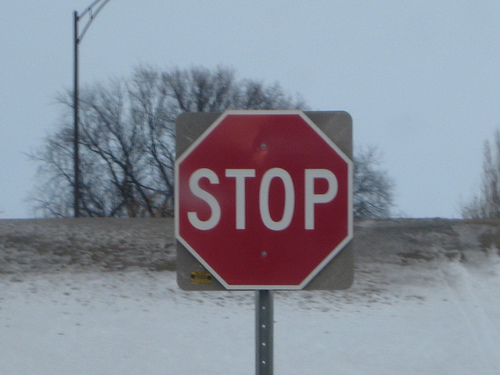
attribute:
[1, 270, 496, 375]
snow — white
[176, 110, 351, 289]
stop sign — red, octagon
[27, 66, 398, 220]
trees — leafless, dry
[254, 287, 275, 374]
pole — silver, emerging from ground, metal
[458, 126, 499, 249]
shrubbery — leafless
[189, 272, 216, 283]
sticker — yellow, black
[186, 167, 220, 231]
letter — s, white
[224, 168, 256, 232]
letter — t, white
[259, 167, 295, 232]
letter — o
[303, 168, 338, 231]
letter — p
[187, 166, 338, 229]
word — stop, white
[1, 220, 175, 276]
grass — brown, dry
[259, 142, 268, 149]
screw — metal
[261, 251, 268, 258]
screw — metal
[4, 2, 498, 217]
sky — bright, clear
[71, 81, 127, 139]
branches — barren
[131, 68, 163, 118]
branches — barren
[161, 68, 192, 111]
branches — barren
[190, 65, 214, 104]
branches — barren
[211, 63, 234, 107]
branches — barren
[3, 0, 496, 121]
clouds — snowy, grey